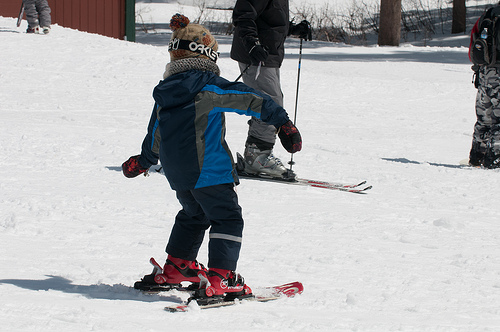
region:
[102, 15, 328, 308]
kids wearing red boots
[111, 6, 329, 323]
child is skiing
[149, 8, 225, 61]
child wearing brown beanie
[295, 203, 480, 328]
ground covered with snow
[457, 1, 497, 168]
person wearing backpack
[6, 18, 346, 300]
child casting shadow behiind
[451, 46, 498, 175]
person wearing camouflage pants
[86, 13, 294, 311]
child wearing black pants with grey stripe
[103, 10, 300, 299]
child wearing mitten gloves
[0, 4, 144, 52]
red structure in background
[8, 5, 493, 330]
People skiing on the snow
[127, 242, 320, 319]
Small red and black skis and boots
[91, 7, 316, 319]
Small child with red skis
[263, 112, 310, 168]
Red and black mitton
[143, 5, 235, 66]
Camouflage winter hat being worn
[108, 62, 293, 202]
Blue and gray winter jacket with hood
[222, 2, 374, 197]
Adult in black jacket skiing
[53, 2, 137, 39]
Red and green building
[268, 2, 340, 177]
Person holding ski poles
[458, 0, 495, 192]
Person wearing black and red backpack with a water bottle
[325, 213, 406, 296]
the snow is white and clear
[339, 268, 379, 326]
the snow is white and clear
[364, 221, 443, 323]
the snow is white and clear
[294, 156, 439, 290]
the snow is white and clear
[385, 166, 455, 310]
the snow is white and clear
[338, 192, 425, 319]
the snow is white and clear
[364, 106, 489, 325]
the snow is white and clear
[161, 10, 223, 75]
child wearing beanie hat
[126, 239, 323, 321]
child wearing red ski boots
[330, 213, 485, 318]
ground covered in snow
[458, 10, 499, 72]
person wearing backpack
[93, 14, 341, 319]
child wearing warm jacket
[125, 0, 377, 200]
man is skiing towards right of picture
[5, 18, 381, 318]
child casting shadow on ground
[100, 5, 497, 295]
a kid at a ski resort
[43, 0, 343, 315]
this child is learning how to ski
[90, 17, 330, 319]
the kid is having trouble keeping their balance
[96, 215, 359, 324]
this kid has on red ski shoes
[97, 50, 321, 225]
he is wearing a blue and gray coat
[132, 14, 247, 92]
the child has on a brown hat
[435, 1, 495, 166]
this person is wearing camoflouge pants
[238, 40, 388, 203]
his ski pants are gray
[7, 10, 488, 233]
the snow is white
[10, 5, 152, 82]
there is a maroon building in the background